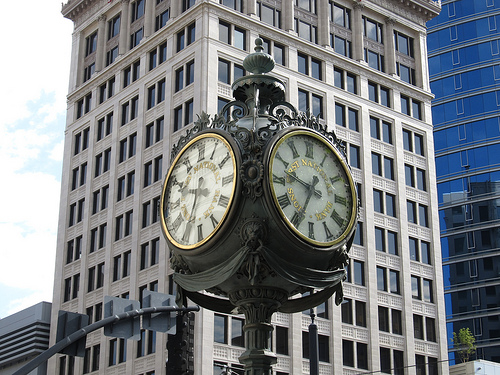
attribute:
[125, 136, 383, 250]
clocks — roman